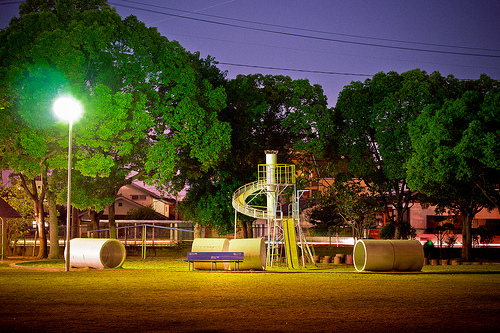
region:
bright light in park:
[26, 66, 101, 138]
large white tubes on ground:
[188, 231, 285, 286]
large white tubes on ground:
[60, 227, 127, 281]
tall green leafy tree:
[325, 52, 405, 237]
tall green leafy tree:
[211, 50, 346, 237]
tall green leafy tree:
[91, 10, 202, 271]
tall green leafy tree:
[31, 11, 101, 256]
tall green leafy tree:
[1, 4, 58, 206]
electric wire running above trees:
[194, 46, 388, 95]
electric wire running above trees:
[157, 3, 498, 58]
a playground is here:
[59, 138, 444, 297]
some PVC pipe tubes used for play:
[51, 230, 430, 280]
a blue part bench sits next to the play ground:
[185, 243, 242, 270]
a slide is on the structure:
[235, 165, 300, 236]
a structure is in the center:
[196, 144, 326, 269]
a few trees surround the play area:
[20, 58, 486, 196]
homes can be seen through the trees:
[18, 171, 490, 232]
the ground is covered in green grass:
[68, 268, 450, 323]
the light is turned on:
[38, 93, 83, 269]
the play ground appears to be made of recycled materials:
[65, 145, 442, 272]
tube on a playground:
[60, 231, 130, 268]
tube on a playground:
[347, 234, 433, 272]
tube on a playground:
[190, 232, 275, 269]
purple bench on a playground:
[181, 247, 249, 275]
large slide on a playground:
[224, 142, 313, 277]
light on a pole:
[45, 88, 92, 280]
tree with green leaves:
[402, 91, 499, 264]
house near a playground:
[75, 172, 185, 234]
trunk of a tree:
[37, 188, 69, 264]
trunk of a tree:
[31, 200, 48, 266]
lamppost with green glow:
[24, 65, 116, 160]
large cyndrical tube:
[55, 223, 149, 275]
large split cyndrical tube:
[345, 226, 451, 276]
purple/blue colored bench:
[177, 235, 249, 277]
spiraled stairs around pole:
[238, 131, 306, 250]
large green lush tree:
[371, 75, 491, 269]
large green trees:
[18, 85, 284, 250]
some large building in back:
[334, 183, 489, 250]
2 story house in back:
[96, 174, 191, 234]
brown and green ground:
[146, 277, 418, 330]